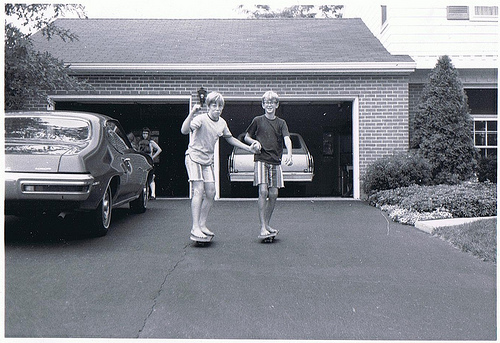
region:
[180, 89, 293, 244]
two boys on skateboards in a driveway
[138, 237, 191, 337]
crack in a paved driveway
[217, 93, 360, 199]
station wagon inside one of two garage bays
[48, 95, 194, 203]
person standing in one of two garage bays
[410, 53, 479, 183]
pine bush in front of a white house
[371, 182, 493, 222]
low growing shrubbery in front of a house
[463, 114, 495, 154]
bay window on the front of the house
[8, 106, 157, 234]
shiny sedan on a driveway in front of a garage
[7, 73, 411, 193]
brick garage with two bays framed in white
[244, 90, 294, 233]
boy wearing striped shorts and dark tee shirt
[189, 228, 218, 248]
Small black skateboard on the ground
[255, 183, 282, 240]
Exposed calves of a person riding a skate board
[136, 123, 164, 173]
Woman standing and putting a hand on her hip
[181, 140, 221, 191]
Short striped shorts being worn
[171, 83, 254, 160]
Young boy raising a hand in the air wearing a t shirt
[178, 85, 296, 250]
Two boys skate boarding and holding hands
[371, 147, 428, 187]
Short bushy dark colored shrub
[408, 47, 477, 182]
Tall well groomed pine tree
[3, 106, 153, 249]
Shiny car with four wheels parked in a driveway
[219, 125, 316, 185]
Car visible behind a boy parked in a garage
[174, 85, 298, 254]
Two young boys on skateboards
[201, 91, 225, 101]
blonde hair on boy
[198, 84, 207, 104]
light on front of garage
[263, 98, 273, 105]
glasses on the boy's face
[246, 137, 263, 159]
the boys' held hands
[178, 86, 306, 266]
two boys skateboarding in driveway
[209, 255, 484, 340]
black cement on the ground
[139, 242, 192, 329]
crack in the cement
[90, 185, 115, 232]
right rear tire on car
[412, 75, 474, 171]
bush next to the house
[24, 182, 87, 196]
right brake light on the car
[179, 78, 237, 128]
head of a person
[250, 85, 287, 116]
head of a person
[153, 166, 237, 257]
leg of a person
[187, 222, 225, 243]
feet of a person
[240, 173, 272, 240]
leg of a person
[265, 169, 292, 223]
leg of a person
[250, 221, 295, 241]
feet of a person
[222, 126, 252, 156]
arm of a person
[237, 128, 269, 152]
arm of a person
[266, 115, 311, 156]
arm of a person